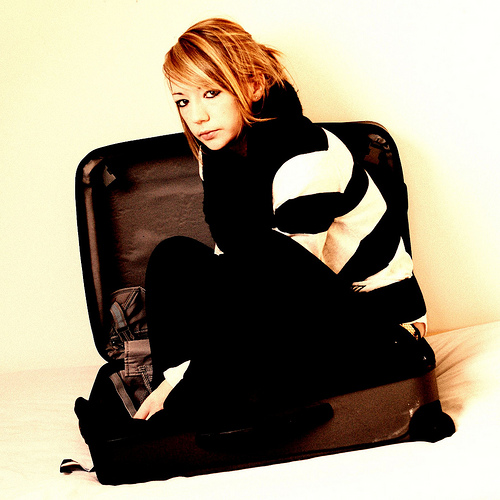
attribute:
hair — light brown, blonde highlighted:
[163, 18, 293, 159]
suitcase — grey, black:
[64, 125, 461, 484]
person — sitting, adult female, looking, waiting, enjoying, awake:
[145, 18, 428, 403]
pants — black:
[145, 228, 422, 400]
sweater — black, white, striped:
[196, 117, 426, 336]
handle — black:
[196, 403, 336, 450]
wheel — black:
[423, 412, 455, 444]